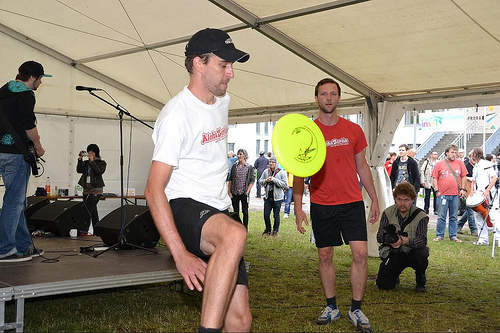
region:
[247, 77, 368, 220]
The frisbee is yellow and in the air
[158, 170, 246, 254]
Man is wearing black shorts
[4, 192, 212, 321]
The stage is in the background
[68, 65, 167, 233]
Microphone on the stage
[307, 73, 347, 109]
The man has brown hair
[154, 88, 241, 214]
The man wears a white shirt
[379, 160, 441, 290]
Man is holding a camera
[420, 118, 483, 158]
Stairs in the background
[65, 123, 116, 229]
Woman taking a picture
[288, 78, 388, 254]
Man wearing a red shirt and black shorts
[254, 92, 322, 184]
The frisbee is yellow.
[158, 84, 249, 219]
This man has a white shirt.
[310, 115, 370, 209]
This man has a red shirt.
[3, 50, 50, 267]
This man is playing an instrument.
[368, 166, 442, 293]
This man is taking a photo.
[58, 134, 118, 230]
This woman is taking a photo.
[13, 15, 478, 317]
This is under a tent.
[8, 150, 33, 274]
This man has blue jeans.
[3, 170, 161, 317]
This is on a stage.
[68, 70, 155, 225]
This is a microphone.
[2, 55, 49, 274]
guy playing a guitar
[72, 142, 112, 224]
woman taking a picture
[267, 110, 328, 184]
yellow frisbee in the air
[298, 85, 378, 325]
man with a red shirt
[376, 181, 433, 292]
guy kneeling on the ground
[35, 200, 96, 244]
speakers for the microphone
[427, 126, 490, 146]
stairs to a building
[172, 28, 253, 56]
black hat the guy is wearing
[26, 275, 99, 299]
stage for the band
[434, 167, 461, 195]
red shirt on the guy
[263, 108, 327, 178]
yellow Frisbee being thrown in the air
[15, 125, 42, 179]
black electric guitar for playing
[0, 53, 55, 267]
man playing the electric guitar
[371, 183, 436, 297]
man taking photo of the man with the Frisbee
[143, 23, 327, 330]
man throwing Frisbee inbetween legs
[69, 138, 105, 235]
person video taping the performance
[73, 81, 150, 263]
black microphone with stand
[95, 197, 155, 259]
sound speakers for guitar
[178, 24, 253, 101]
man wearing a black hat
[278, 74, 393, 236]
man wearing orange shirt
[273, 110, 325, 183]
A yellow frisbee in the air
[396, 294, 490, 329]
Grass inside of the tent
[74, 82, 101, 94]
A microphone on the stage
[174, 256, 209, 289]
The right hand of the man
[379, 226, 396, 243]
A black camera in the man's hands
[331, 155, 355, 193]
The man's shirt is red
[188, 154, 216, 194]
The man's shirt is white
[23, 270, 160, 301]
A stage below the microphone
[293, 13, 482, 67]
The roof of the tent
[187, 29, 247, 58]
The man has a black hat